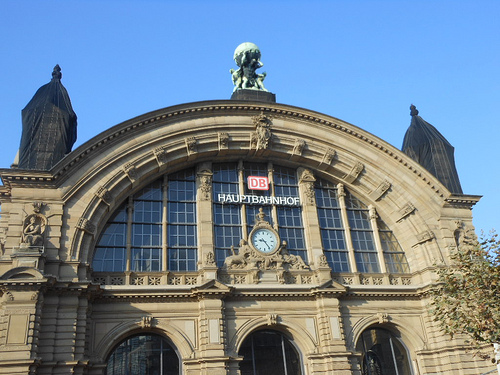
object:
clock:
[248, 226, 280, 257]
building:
[1, 43, 498, 374]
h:
[214, 193, 224, 203]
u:
[230, 193, 241, 203]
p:
[240, 194, 247, 204]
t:
[244, 194, 255, 203]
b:
[250, 194, 259, 205]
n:
[274, 196, 280, 204]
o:
[286, 197, 293, 205]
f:
[294, 196, 300, 205]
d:
[250, 176, 258, 187]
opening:
[234, 323, 309, 374]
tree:
[424, 222, 498, 369]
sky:
[0, 2, 499, 153]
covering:
[17, 62, 79, 170]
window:
[89, 160, 414, 276]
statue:
[227, 42, 267, 100]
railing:
[89, 272, 417, 291]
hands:
[253, 238, 271, 248]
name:
[215, 192, 300, 208]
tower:
[402, 104, 460, 199]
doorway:
[101, 326, 181, 373]